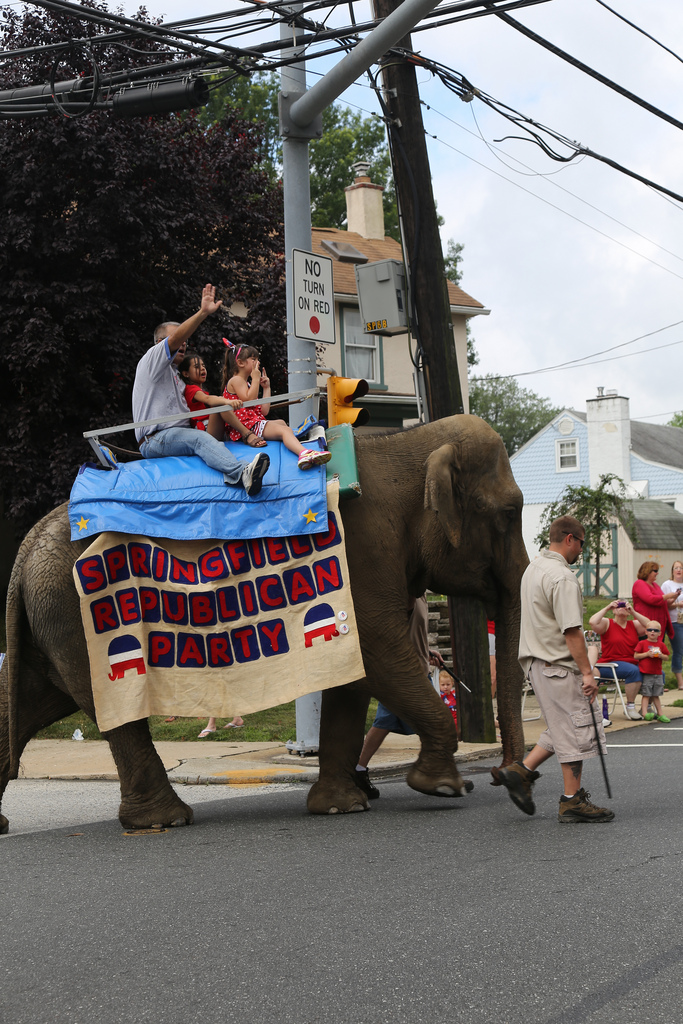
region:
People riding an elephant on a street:
[0, 279, 536, 837]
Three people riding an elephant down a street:
[1, 279, 533, 839]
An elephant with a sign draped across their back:
[0, 413, 533, 838]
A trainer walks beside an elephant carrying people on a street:
[490, 514, 620, 828]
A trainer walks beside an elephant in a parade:
[487, 515, 620, 830]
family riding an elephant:
[0, 275, 547, 837]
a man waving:
[118, 275, 280, 502]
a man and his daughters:
[124, 273, 334, 504]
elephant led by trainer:
[1, 381, 628, 846]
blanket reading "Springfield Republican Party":
[70, 468, 372, 744]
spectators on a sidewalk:
[580, 551, 681, 731]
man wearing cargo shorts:
[486, 500, 630, 832]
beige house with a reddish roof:
[281, 152, 496, 417]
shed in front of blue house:
[506, 385, 681, 605]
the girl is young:
[220, 340, 331, 470]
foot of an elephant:
[303, 773, 372, 815]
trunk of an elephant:
[494, 611, 524, 767]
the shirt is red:
[593, 618, 633, 663]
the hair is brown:
[550, 515, 584, 546]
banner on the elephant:
[73, 480, 364, 731]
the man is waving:
[130, 281, 269, 498]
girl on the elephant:
[173, 352, 267, 444]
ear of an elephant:
[423, 445, 462, 546]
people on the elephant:
[81, 258, 357, 514]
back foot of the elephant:
[98, 755, 231, 870]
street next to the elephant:
[161, 851, 404, 969]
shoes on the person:
[470, 723, 642, 853]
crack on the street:
[560, 826, 681, 904]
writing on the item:
[57, 498, 352, 698]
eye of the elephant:
[477, 469, 545, 550]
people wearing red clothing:
[564, 558, 679, 711]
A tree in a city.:
[160, 37, 463, 291]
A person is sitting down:
[588, 587, 647, 722]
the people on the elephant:
[0, 284, 530, 836]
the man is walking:
[500, 514, 614, 822]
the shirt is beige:
[518, 548, 588, 664]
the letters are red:
[71, 477, 367, 736]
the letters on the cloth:
[70, 477, 367, 734]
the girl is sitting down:
[221, 337, 332, 469]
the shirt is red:
[599, 617, 638, 665]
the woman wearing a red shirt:
[587, 600, 648, 719]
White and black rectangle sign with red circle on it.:
[290, 247, 338, 346]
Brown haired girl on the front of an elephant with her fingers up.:
[222, 336, 333, 467]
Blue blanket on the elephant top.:
[70, 439, 331, 542]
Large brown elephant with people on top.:
[0, 413, 531, 836]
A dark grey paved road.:
[7, 722, 681, 1022]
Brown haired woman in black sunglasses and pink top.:
[636, 560, 681, 642]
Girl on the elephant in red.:
[176, 354, 267, 446]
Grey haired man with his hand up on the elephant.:
[133, 280, 270, 496]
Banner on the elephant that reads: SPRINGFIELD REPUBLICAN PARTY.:
[71, 476, 364, 732]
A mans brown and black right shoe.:
[557, 789, 615, 825]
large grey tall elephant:
[0, 411, 533, 834]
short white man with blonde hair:
[497, 518, 616, 821]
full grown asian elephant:
[0, 409, 530, 834]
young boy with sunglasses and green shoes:
[633, 619, 671, 723]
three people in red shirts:
[595, 568, 673, 683]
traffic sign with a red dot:
[292, 245, 337, 344]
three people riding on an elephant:
[127, 274, 332, 494]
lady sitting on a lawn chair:
[587, 595, 661, 729]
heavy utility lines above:
[6, 11, 682, 249]